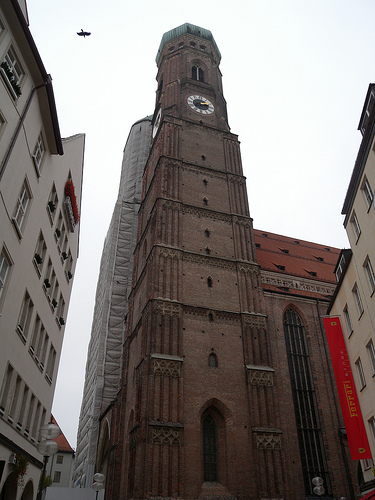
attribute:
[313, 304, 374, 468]
flag — red, large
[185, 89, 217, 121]
clock — white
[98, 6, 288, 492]
church — brown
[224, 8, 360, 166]
sky — white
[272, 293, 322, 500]
window — gated, arch shape, large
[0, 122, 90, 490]
building — white, modern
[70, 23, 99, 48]
bird — black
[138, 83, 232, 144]
circles — silver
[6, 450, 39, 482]
bush — green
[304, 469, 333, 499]
round shades — clear, glass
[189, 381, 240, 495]
window — arched, deep arched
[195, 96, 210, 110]
hands — golden, yellow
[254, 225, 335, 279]
roof — red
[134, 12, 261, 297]
tower — brown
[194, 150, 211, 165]
window — tiny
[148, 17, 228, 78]
roof — metal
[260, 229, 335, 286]
roof — red